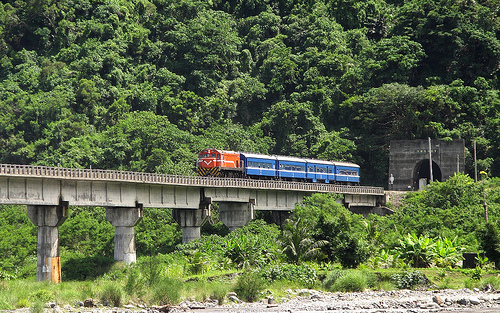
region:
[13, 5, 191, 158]
trees with green leaves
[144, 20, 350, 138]
trees with green leaves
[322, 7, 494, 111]
trees with green leaves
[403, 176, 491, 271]
trees with green leaves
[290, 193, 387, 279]
trees with green leaves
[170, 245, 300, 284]
trees with green leaves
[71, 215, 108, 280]
trees with green leaves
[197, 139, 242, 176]
red train engine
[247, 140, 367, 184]
blue and gray train cars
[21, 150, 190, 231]
gray bridge with train tracks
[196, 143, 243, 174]
orange train engine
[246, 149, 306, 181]
blue and white train cars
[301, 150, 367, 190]
blue and white train cars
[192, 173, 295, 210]
gray bridge with train tracks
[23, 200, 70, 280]
gray bridge with train tracks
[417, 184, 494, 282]
brown bushes with green leaves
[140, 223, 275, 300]
brown bushes with green leaves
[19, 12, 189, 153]
brown bushes with green leaves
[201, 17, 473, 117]
brown bushes with green leaves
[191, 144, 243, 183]
orange engine car on train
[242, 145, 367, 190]
blue cars of passenger train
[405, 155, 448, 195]
dark archway over train tracks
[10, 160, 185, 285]
bridge for railroad tracks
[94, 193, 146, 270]
pole under railroad bridge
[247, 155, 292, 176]
windows on train car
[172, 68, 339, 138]
trees on hill behind bridge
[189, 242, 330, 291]
vegetation below railroad bridge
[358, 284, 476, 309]
dirt and rocks in front of vegetation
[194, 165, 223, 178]
black and yellow bumper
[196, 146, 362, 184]
A train on tracks.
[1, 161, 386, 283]
A grey stone bridge.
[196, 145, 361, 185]
Five cars on tracks.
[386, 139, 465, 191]
A tunnel in the mountains.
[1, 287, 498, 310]
Gravel on the ground.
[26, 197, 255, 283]
Four pillars under bridge.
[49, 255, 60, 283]
A yellow door on pillar.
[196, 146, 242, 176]
An orange train engine.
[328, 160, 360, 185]
A blue train caboose.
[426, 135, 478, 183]
Three poles by a tunnel.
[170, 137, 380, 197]
The train is on tracks.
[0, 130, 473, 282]
The train is crossing a bridge.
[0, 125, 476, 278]
The bridge is made of stone and metal.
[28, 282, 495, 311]
Rocks are under the bridge.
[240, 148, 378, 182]
The train's cars are blue.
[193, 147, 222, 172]
The train is red.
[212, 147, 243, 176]
The train is orange.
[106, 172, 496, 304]
Grass and shrubs are under the bridge.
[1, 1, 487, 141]
Trees are behind the bridge.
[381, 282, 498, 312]
Water is under the bridge.